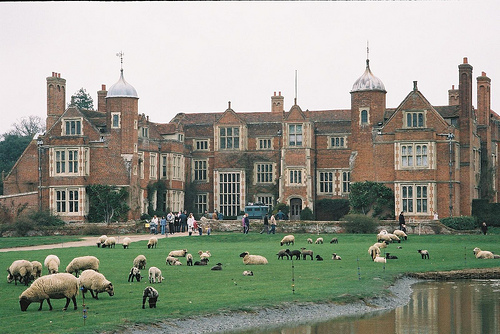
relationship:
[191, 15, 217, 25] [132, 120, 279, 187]
sky behind building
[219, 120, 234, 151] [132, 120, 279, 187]
window of building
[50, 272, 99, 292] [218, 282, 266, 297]
sheep on grass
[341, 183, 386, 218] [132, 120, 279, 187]
tree in front of building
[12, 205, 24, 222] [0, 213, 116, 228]
pole of fence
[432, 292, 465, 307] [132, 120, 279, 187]
water in front of building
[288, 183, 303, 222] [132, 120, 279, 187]
door of building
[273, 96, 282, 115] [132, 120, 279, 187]
chimney of building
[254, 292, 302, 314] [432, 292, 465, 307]
rocks around water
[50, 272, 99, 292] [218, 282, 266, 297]
sheep in grass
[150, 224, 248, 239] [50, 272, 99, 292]
people near sheep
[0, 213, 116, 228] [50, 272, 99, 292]
fence between sheep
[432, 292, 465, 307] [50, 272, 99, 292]
water near sheep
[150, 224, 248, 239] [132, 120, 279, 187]
people near building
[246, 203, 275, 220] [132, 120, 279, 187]
car near building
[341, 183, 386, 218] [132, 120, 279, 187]
tree near building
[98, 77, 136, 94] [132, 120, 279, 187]
dome on building